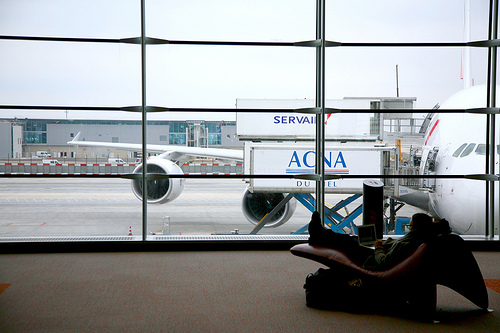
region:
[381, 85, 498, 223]
A plane at the terminal.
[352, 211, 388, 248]
the laptop in a person lap.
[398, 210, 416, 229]
The man is wearing glasses.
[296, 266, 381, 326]
The bags on the floor.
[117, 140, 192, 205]
The engine on the plane.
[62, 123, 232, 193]
The wing on the plane.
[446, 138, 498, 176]
Cockpit on the plane.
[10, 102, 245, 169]
A building on the airport.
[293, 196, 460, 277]
A person is sitting on the chair.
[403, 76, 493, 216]
The plane is white.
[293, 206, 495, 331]
person relaxing on a chair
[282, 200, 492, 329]
woman relaxing in an airport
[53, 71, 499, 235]
airplane through a blank of windows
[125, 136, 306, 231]
two airplane engines on wing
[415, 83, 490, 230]
airplain fuselage through window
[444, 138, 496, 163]
small windows on front of airplane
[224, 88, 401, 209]
storage containers used to restock plane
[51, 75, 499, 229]
plane preparing for next flight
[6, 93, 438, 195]
long building behind plane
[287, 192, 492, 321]
woman lounging on chair at airport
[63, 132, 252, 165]
wing of airplane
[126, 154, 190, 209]
airplane engine mounted under wing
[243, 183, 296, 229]
second airplane engine mounted under wing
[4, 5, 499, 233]
airport terminal windows looking out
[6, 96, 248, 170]
building at airport across from terminal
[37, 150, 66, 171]
offical work trucks at airport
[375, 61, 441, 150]
air traffic control tower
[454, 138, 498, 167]
window to the cockpit of the airplane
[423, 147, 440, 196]
door open on side of plane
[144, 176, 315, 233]
glass window in airport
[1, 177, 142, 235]
glass window in airport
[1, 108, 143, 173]
glass window in airport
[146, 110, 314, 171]
glass window in airport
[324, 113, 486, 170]
glass window in airport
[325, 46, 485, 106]
glass window in airport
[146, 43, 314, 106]
glass window in airport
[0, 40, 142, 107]
glass window in airport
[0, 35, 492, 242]
glass windows in airport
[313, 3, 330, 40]
silver metal window frame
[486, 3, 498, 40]
silver metal window frame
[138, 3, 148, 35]
silver metal window frame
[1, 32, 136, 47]
silver metal window frame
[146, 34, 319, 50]
silver metal window frame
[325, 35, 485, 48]
silver metal window frame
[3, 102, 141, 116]
silver metal window frame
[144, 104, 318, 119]
silver metal window frame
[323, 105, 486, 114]
silver metal window frame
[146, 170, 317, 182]
silver metal window frame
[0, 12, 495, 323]
a scene in the airport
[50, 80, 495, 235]
a white large plane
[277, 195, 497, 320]
people sitting down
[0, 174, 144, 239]
glass window on building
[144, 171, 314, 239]
glass window on building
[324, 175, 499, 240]
glass window on building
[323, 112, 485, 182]
glass window on building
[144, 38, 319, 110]
glass window on building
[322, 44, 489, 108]
glass window on building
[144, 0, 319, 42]
glass window on building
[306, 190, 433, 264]
person reclining by the window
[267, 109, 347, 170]
blue lettering on white background